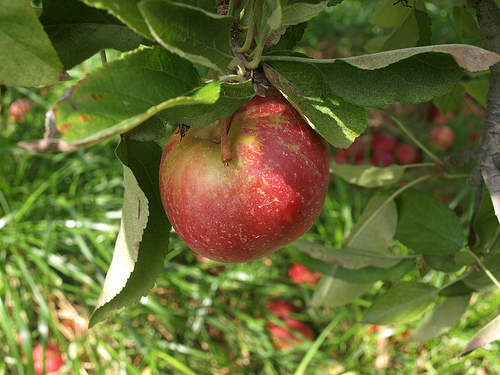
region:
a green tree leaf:
[85, 111, 160, 329]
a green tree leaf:
[292, 237, 416, 282]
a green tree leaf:
[351, 280, 448, 337]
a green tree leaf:
[405, 285, 476, 352]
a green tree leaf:
[459, 317, 499, 361]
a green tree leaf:
[392, 175, 473, 263]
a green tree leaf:
[311, 197, 393, 314]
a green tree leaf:
[326, 155, 411, 195]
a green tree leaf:
[299, 37, 497, 124]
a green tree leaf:
[39, 50, 219, 151]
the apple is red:
[158, 95, 412, 306]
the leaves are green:
[51, 16, 493, 238]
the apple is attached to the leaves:
[112, 38, 452, 292]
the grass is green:
[20, 193, 174, 349]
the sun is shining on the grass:
[20, 196, 174, 368]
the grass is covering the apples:
[26, 263, 239, 370]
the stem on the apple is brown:
[211, 118, 240, 168]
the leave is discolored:
[37, 76, 148, 181]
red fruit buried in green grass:
[9, 319, 99, 373]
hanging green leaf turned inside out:
[89, 146, 155, 332]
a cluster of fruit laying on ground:
[331, 93, 473, 170]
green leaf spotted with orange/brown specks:
[25, 81, 119, 162]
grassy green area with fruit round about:
[5, 158, 77, 238]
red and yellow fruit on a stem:
[154, 96, 219, 177]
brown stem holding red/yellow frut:
[201, 113, 253, 172]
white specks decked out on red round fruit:
[186, 165, 334, 265]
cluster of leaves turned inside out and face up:
[301, 182, 469, 331]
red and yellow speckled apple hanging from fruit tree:
[138, 74, 359, 279]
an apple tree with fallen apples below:
[12, 26, 449, 369]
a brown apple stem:
[205, 96, 247, 166]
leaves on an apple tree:
[17, 22, 479, 153]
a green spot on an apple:
[159, 107, 250, 201]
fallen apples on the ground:
[254, 256, 331, 363]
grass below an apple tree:
[10, 195, 184, 367]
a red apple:
[165, 90, 342, 268]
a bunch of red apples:
[334, 100, 462, 176]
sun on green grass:
[29, 193, 154, 373]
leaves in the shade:
[321, 117, 486, 329]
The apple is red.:
[158, 141, 329, 283]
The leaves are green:
[41, 36, 253, 142]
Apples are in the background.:
[340, 106, 465, 181]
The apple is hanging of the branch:
[167, 35, 323, 250]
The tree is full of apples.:
[28, 63, 429, 344]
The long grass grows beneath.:
[37, 203, 185, 343]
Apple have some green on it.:
[170, 137, 275, 188]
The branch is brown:
[470, 80, 497, 192]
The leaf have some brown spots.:
[50, 70, 115, 130]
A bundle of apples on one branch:
[343, 131, 432, 186]